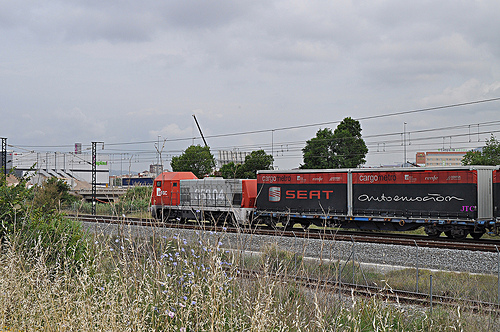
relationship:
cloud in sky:
[7, 4, 499, 140] [4, 7, 499, 169]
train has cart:
[138, 147, 495, 239] [248, 169, 350, 218]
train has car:
[138, 147, 495, 239] [347, 160, 495, 238]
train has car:
[138, 147, 495, 239] [149, 165, 256, 222]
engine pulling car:
[146, 167, 258, 225] [251, 159, 353, 221]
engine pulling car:
[146, 167, 258, 225] [347, 160, 495, 238]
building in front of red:
[16, 115, 148, 240] [144, 168, 193, 211]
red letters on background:
[286, 186, 338, 208] [254, 171, 349, 215]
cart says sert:
[248, 163, 492, 225] [280, 185, 335, 201]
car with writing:
[347, 155, 497, 233] [355, 189, 463, 202]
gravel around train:
[75, 214, 500, 261] [148, 163, 498, 241]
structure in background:
[10, 101, 142, 224] [1, 4, 462, 234]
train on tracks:
[149, 164, 495, 239] [54, 207, 498, 252]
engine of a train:
[143, 167, 262, 221] [148, 163, 498, 241]